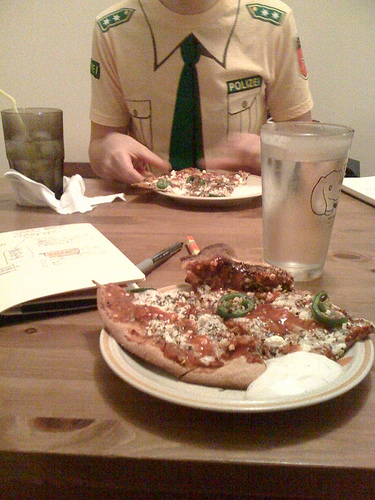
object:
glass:
[260, 122, 354, 283]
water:
[261, 143, 354, 268]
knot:
[32, 416, 97, 432]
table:
[2, 177, 375, 499]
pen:
[136, 241, 183, 274]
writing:
[1, 235, 88, 270]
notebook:
[0, 220, 145, 317]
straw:
[0, 86, 31, 141]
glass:
[1, 107, 66, 210]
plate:
[99, 280, 374, 411]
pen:
[184, 235, 203, 257]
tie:
[169, 32, 206, 173]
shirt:
[89, 1, 313, 179]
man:
[89, 0, 313, 184]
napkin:
[2, 167, 126, 216]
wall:
[0, 0, 373, 180]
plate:
[149, 168, 264, 206]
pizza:
[92, 278, 374, 389]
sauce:
[246, 349, 345, 401]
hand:
[89, 132, 173, 185]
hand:
[196, 131, 264, 175]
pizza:
[134, 165, 250, 199]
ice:
[7, 129, 61, 174]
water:
[7, 136, 63, 199]